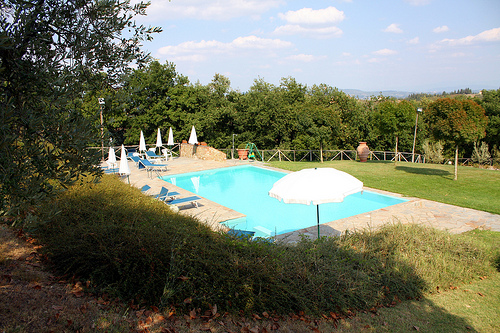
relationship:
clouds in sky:
[124, 8, 481, 83] [2, 2, 499, 104]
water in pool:
[177, 167, 397, 243] [159, 159, 397, 237]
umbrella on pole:
[275, 164, 360, 209] [314, 206, 324, 243]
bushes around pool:
[45, 168, 468, 333] [159, 159, 397, 237]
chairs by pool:
[127, 151, 248, 238] [159, 159, 397, 237]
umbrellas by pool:
[138, 126, 198, 170] [159, 159, 397, 237]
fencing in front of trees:
[88, 143, 499, 172] [72, 52, 500, 158]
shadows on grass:
[399, 162, 449, 190] [275, 154, 499, 220]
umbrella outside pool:
[275, 164, 360, 209] [159, 159, 397, 237]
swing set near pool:
[243, 140, 265, 164] [159, 159, 397, 237]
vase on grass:
[356, 141, 371, 161] [275, 154, 499, 220]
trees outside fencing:
[72, 52, 500, 158] [88, 143, 499, 172]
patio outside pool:
[110, 154, 499, 252] [159, 159, 397, 237]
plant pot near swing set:
[234, 150, 251, 163] [243, 140, 265, 164]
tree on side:
[3, 1, 168, 251] [1, 2, 201, 333]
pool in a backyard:
[159, 159, 397, 237] [6, 144, 496, 332]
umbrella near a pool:
[275, 164, 360, 209] [159, 159, 397, 237]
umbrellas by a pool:
[138, 126, 198, 170] [159, 159, 397, 237]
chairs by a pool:
[127, 151, 248, 238] [159, 159, 397, 237]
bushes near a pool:
[45, 168, 468, 333] [159, 159, 397, 237]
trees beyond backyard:
[72, 52, 500, 158] [6, 144, 496, 332]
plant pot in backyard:
[234, 150, 251, 163] [6, 144, 496, 332]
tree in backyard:
[3, 1, 168, 251] [6, 144, 496, 332]